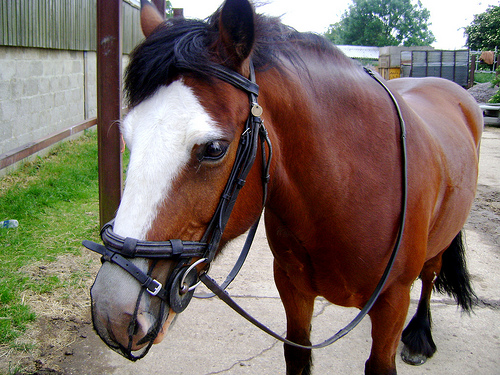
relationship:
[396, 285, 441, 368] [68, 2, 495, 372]
hoof on horse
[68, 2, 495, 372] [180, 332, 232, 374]
horse standing in staples